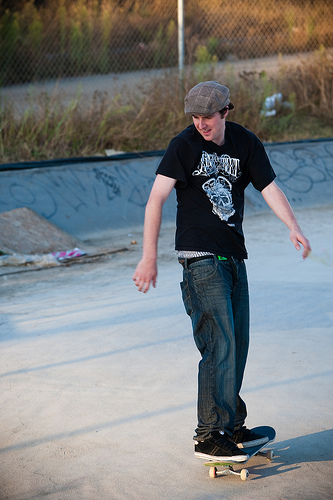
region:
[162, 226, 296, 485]
Young man wearing blue jeans.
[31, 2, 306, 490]
Young man skateboarding.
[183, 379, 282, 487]
Young man wearing black shoes with white soles.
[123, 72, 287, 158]
Young man wearing a hat.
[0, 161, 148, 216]
Graffiti on the concrete.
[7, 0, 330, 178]
Chain link fence behind the skateboarder.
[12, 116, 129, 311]
Trash thrown around on the ground.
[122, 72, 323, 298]
Young man wearing a black t-shirt with white design.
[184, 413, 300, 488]
Three wheels showing on skateboard.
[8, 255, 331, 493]
There are shadows on the ground.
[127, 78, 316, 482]
A man on a skateboard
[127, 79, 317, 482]
A man wearing a hat while riding a skateboard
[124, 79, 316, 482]
A skateboard rider who is smiling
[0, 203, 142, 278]
Garbage on the outskirts of a skateboard area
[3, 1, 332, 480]
A man skateboarding in a fenced in area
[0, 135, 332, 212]
Graffiti written on the side of a skateboard area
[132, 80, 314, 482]
A skateboarder wearing baggy pants and black tennis shoes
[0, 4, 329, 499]
A close up shot of a skateboarder in action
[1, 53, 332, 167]
Trash on the roadside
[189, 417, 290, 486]
A skateboard with small wheels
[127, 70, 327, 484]
a guy riding a skateboard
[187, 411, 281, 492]
the shoes are black and white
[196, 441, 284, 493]
the skateboard has white wheels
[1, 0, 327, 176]
a fence is behind the skateboarder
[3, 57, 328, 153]
the grass is brown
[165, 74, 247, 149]
he is wearing a hat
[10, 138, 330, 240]
the skate ramp has graffiti on it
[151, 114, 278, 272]
his shirt is black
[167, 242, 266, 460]
he is wearing his blue jeans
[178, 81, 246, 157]
the guy is smiling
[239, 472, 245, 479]
wheels of a skateboard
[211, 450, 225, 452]
part of a black shoe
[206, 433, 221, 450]
right foot of a man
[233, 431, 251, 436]
left foot of a man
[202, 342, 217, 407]
section of a blue jeans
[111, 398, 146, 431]
section of a skating surface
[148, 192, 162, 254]
right hand of a man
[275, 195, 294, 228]
left arm of a skater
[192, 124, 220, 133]
face of a skater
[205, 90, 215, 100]
section of a hat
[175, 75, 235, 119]
A checkered gray hat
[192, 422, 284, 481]
Black shoes riding a skateboard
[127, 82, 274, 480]
A boy riding in a skatepark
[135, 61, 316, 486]
A boy riding a skateboard in a skate park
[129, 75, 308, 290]
A boy with his hands extended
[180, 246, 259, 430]
A boy wearing a belt and saggy pants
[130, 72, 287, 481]
A boy skateboarding wearing blue jeans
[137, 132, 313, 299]
A boy wearing a black shirt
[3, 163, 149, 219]
skate park with grafftti written on it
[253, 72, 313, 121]
White litter in tall grass